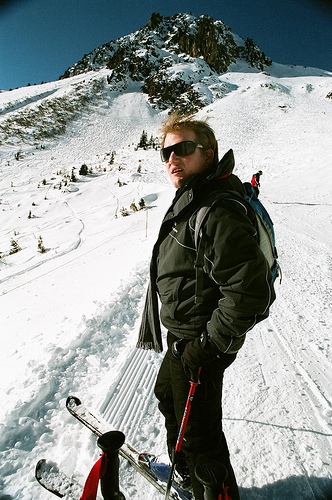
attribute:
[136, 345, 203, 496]
pole — red , black ski 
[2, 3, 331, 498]
mountain — snow-covered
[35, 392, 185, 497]
skis — pair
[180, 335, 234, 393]
gloves — black, winter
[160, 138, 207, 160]
sunglasses — pair, black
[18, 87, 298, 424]
snow — white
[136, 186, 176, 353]
scarf — dark grey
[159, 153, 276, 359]
jacket — black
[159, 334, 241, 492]
pants — black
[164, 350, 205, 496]
pole — ski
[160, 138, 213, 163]
sunglasses — black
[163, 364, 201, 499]
ski pole — red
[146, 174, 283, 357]
jacket — black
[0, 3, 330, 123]
mountain — large, snowy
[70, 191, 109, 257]
snow — white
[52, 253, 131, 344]
snow — white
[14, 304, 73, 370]
snow — white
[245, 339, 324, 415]
snow — white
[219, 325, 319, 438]
snow — white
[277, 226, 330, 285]
snow — white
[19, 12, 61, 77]
sky — clear, blue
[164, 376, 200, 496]
stick — ski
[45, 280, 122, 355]
snow — color, white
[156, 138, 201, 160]
glasses — sun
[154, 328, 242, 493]
pair — of black winter pants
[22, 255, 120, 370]
snow — covering the ground